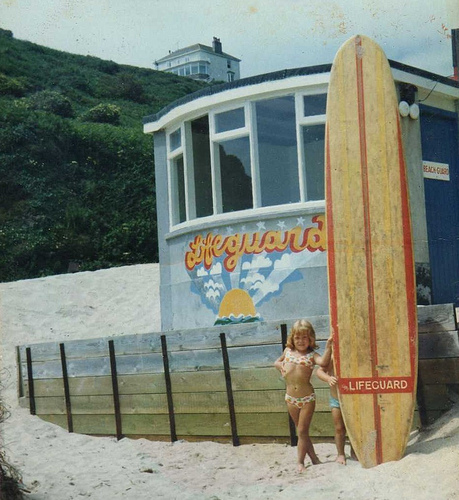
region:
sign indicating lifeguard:
[337, 374, 411, 394]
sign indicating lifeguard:
[168, 209, 331, 273]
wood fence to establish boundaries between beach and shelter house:
[5, 319, 450, 451]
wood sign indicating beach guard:
[419, 156, 453, 184]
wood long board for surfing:
[317, 27, 428, 474]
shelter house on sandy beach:
[120, 55, 453, 353]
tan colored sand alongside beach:
[7, 253, 443, 494]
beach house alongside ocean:
[143, 26, 256, 90]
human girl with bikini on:
[273, 308, 328, 467]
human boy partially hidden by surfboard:
[318, 314, 360, 464]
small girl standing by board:
[265, 20, 418, 461]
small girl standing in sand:
[267, 318, 343, 483]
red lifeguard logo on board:
[335, 375, 413, 402]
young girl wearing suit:
[263, 310, 338, 468]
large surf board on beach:
[288, 24, 434, 469]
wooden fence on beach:
[15, 324, 264, 434]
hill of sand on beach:
[0, 255, 144, 445]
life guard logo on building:
[160, 214, 337, 293]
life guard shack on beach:
[123, 57, 423, 327]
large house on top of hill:
[147, 31, 249, 84]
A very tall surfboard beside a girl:
[321, 33, 419, 467]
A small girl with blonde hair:
[272, 317, 336, 471]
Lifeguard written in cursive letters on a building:
[185, 212, 328, 271]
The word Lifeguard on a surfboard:
[343, 379, 407, 390]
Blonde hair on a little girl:
[285, 319, 319, 352]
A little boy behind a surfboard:
[318, 335, 355, 464]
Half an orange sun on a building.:
[215, 286, 256, 316]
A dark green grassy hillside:
[2, 27, 216, 286]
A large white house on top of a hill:
[152, 35, 241, 85]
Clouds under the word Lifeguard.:
[192, 252, 292, 299]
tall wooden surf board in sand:
[319, 31, 428, 462]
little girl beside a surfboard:
[270, 313, 330, 466]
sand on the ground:
[56, 284, 126, 312]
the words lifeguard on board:
[345, 380, 410, 394]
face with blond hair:
[289, 316, 319, 350]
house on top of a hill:
[153, 29, 253, 82]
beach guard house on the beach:
[420, 156, 453, 180]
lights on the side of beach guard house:
[401, 104, 431, 121]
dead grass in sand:
[5, 450, 50, 492]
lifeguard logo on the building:
[182, 214, 336, 322]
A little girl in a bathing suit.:
[276, 316, 331, 470]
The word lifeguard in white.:
[335, 375, 414, 392]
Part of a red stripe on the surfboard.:
[360, 204, 375, 291]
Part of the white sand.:
[142, 440, 207, 481]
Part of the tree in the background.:
[44, 142, 118, 229]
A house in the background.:
[157, 40, 242, 83]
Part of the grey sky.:
[79, 12, 162, 40]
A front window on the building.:
[252, 92, 300, 202]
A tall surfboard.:
[324, 31, 417, 465]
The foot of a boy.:
[332, 451, 347, 465]